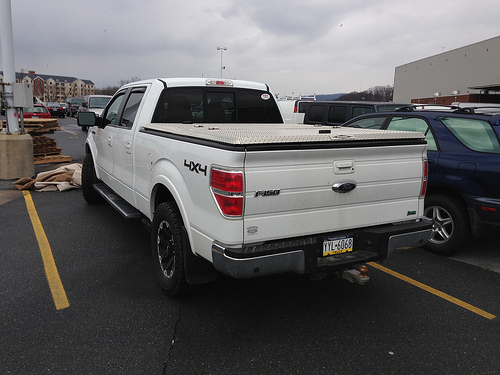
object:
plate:
[322, 238, 353, 256]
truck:
[76, 77, 435, 298]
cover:
[141, 123, 426, 148]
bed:
[134, 127, 429, 249]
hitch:
[342, 268, 370, 285]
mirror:
[77, 112, 96, 126]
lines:
[20, 190, 71, 312]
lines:
[59, 126, 77, 135]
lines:
[364, 260, 497, 320]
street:
[1, 115, 499, 374]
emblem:
[332, 180, 356, 193]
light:
[206, 80, 233, 86]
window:
[150, 86, 284, 124]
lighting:
[217, 47, 220, 51]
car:
[17, 104, 51, 119]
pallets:
[1, 118, 58, 123]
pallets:
[33, 155, 72, 164]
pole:
[1, 1, 21, 135]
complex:
[1, 70, 95, 106]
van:
[303, 101, 413, 127]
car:
[339, 110, 500, 255]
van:
[275, 100, 315, 124]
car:
[46, 103, 67, 119]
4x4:
[184, 159, 208, 177]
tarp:
[12, 162, 83, 191]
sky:
[2, 1, 500, 95]